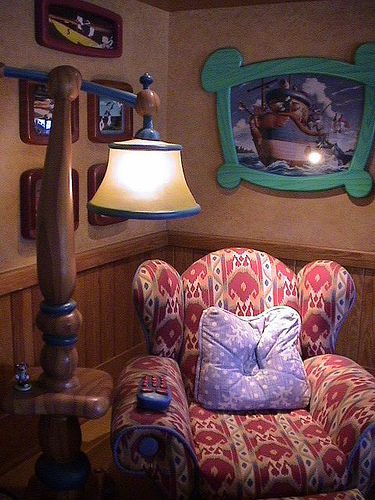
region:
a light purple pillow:
[167, 284, 323, 424]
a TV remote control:
[131, 364, 173, 423]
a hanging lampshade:
[94, 115, 203, 238]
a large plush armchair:
[125, 250, 370, 488]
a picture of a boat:
[193, 41, 373, 221]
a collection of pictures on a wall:
[0, 0, 156, 223]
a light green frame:
[178, 27, 367, 211]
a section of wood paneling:
[2, 245, 359, 457]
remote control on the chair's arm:
[139, 367, 169, 403]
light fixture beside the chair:
[6, 55, 187, 491]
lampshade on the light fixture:
[85, 128, 206, 220]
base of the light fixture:
[10, 466, 106, 498]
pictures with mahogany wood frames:
[15, 1, 143, 232]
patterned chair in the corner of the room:
[111, 244, 367, 497]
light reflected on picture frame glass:
[301, 145, 325, 171]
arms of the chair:
[113, 353, 374, 487]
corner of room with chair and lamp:
[0, 1, 372, 498]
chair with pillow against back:
[113, 245, 374, 497]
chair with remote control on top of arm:
[112, 248, 373, 498]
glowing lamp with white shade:
[0, 58, 199, 498]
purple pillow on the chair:
[196, 308, 303, 398]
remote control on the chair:
[132, 363, 172, 411]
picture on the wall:
[189, 24, 372, 207]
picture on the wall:
[33, 2, 126, 61]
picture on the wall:
[89, 75, 136, 140]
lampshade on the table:
[77, 132, 203, 223]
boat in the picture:
[242, 89, 337, 173]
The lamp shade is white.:
[106, 137, 182, 205]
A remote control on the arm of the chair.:
[134, 368, 171, 412]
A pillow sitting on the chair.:
[204, 315, 300, 407]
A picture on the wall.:
[44, 2, 128, 66]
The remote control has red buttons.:
[143, 373, 160, 385]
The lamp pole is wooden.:
[46, 76, 74, 377]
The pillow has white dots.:
[214, 358, 282, 405]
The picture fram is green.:
[210, 52, 373, 196]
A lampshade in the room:
[86, 130, 200, 222]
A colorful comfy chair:
[115, 246, 368, 474]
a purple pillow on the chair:
[194, 304, 314, 414]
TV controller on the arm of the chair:
[134, 364, 175, 417]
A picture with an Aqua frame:
[199, 32, 372, 212]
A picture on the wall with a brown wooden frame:
[24, 4, 141, 64]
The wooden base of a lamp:
[14, 417, 109, 490]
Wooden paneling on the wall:
[85, 241, 129, 355]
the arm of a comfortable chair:
[107, 351, 190, 476]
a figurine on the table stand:
[11, 357, 34, 396]